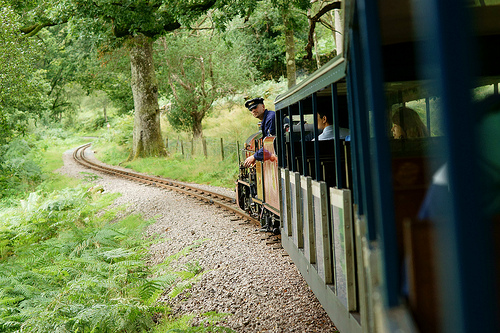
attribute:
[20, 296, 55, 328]
grass — short, green, brown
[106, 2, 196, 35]
leaves — green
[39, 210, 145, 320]
leaves — green 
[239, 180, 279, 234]
wheels — black, round, small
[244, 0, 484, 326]
train — medium, black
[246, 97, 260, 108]
hat — black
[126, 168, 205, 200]
train tracks — rusted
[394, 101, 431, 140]
hair — long